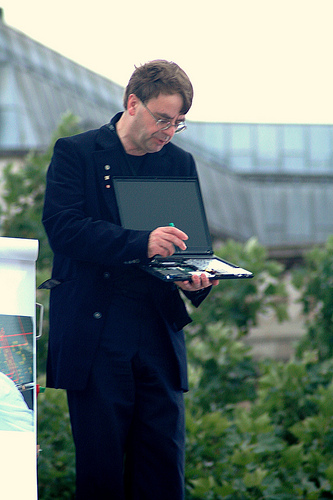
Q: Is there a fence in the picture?
A: No, there are no fences.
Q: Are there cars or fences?
A: No, there are no fences or cars.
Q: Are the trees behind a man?
A: Yes, the trees are behind a man.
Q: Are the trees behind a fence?
A: No, the trees are behind a man.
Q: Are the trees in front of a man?
A: No, the trees are behind a man.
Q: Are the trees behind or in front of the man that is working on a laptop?
A: The trees are behind the man.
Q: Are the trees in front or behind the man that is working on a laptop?
A: The trees are behind the man.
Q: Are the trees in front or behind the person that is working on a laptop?
A: The trees are behind the man.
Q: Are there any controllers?
A: No, there are no controllers.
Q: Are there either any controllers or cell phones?
A: No, there are no controllers or cell phones.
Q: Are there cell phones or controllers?
A: No, there are no controllers or cell phones.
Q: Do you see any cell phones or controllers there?
A: No, there are no controllers or cell phones.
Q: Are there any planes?
A: No, there are no planes.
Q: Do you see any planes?
A: No, there are no planes.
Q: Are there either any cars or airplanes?
A: No, there are no airplanes or cars.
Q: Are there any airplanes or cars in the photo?
A: No, there are no airplanes or cars.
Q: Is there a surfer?
A: No, there are no surfers.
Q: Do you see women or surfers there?
A: No, there are no surfers or women.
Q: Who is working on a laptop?
A: The man is working on a laptop.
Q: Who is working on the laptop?
A: The man is working on a laptop.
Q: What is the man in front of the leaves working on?
A: The man is working on a laptop.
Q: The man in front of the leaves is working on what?
A: The man is working on a laptop.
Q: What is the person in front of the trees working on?
A: The man is working on a laptop.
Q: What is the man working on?
A: The man is working on a laptop.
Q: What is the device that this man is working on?
A: The device is a laptop.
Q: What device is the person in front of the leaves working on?
A: The man is working on a laptop.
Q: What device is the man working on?
A: The man is working on a laptop.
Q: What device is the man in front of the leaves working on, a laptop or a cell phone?
A: The man is working on a laptop.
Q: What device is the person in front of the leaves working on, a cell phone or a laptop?
A: The man is working on a laptop.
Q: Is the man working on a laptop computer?
A: Yes, the man is working on a laptop computer.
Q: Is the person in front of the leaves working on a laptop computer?
A: Yes, the man is working on a laptop computer.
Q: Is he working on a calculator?
A: No, the man is working on a laptop computer.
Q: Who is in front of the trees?
A: The man is in front of the trees.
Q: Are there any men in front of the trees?
A: Yes, there is a man in front of the trees.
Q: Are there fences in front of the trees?
A: No, there is a man in front of the trees.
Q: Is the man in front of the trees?
A: Yes, the man is in front of the trees.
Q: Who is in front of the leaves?
A: The man is in front of the leaves.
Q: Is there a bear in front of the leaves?
A: No, there is a man in front of the leaves.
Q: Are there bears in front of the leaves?
A: No, there is a man in front of the leaves.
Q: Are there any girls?
A: No, there are no girls.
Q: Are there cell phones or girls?
A: No, there are no girls or cell phones.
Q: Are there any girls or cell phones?
A: No, there are no girls or cell phones.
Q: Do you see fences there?
A: No, there are no fences.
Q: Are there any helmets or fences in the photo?
A: No, there are no fences or helmets.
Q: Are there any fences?
A: No, there are no fences.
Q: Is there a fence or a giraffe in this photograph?
A: No, there are no fences or giraffes.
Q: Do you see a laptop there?
A: Yes, there is a laptop.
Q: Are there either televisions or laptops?
A: Yes, there is a laptop.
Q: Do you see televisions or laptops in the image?
A: Yes, there is a laptop.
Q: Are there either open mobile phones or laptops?
A: Yes, there is an open laptop.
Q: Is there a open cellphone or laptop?
A: Yes, there is an open laptop.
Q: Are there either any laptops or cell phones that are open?
A: Yes, the laptop is open.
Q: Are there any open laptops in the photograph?
A: Yes, there is an open laptop.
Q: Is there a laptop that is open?
A: Yes, there is a laptop that is open.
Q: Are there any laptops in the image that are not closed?
A: Yes, there is a open laptop.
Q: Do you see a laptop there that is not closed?
A: Yes, there is a open laptop.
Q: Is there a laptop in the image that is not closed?
A: Yes, there is a open laptop.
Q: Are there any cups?
A: No, there are no cups.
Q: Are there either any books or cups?
A: No, there are no cups or books.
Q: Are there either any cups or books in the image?
A: No, there are no cups or books.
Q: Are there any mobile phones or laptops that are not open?
A: No, there is a laptop but it is open.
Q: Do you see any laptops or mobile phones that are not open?
A: No, there is a laptop but it is open.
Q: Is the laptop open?
A: Yes, the laptop is open.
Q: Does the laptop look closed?
A: No, the laptop is open.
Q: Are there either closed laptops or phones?
A: No, there is a laptop but it is open.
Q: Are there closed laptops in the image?
A: No, there is a laptop but it is open.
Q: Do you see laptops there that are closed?
A: No, there is a laptop but it is open.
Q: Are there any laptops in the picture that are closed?
A: No, there is a laptop but it is open.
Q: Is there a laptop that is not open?
A: No, there is a laptop but it is open.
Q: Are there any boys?
A: No, there are no boys.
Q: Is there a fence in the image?
A: No, there are no fences.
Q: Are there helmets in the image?
A: No, there are no helmets.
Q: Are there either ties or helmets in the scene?
A: No, there are no helmets or ties.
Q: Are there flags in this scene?
A: No, there are no flags.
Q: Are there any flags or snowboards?
A: No, there are no flags or snowboards.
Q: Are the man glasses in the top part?
A: Yes, the glasses are in the top of the image.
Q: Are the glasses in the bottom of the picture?
A: No, the glasses are in the top of the image.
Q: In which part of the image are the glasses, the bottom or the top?
A: The glasses are in the top of the image.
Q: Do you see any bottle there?
A: No, there are no bottles.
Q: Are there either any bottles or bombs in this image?
A: No, there are no bottles or bombs.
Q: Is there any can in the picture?
A: No, there are no cans.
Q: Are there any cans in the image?
A: No, there are no cans.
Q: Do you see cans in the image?
A: No, there are no cans.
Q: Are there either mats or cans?
A: No, there are no cans or mats.